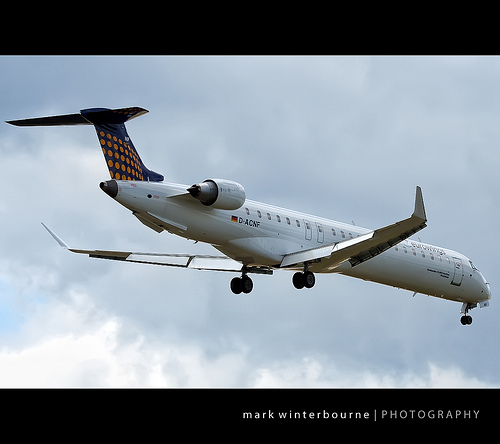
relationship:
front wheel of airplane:
[460, 310, 471, 326] [2, 105, 492, 327]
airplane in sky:
[38, 130, 468, 307] [1, 55, 499, 389]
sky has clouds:
[1, 55, 499, 389] [2, 264, 491, 389]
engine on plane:
[171, 159, 265, 239] [31, 86, 485, 312]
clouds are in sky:
[2, 53, 499, 388] [1, 55, 499, 389]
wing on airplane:
[43, 223, 252, 274] [2, 105, 492, 327]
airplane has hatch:
[2, 105, 492, 327] [451, 255, 464, 285]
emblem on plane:
[215, 204, 283, 249] [129, 106, 497, 336]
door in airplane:
[452, 255, 462, 285] [2, 105, 492, 327]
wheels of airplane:
[286, 263, 318, 288] [2, 105, 492, 327]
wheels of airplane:
[227, 273, 254, 297] [2, 105, 492, 327]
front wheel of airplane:
[459, 314, 473, 325] [2, 105, 492, 327]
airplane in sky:
[2, 105, 492, 327] [34, 278, 399, 374]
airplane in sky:
[2, 105, 492, 327] [306, 81, 404, 137]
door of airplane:
[303, 217, 311, 240] [2, 105, 492, 327]